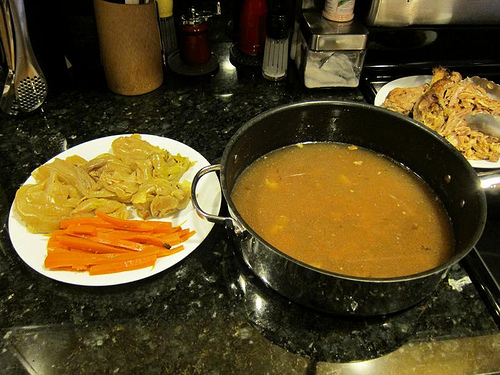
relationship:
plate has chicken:
[375, 73, 499, 171] [398, 74, 469, 119]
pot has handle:
[224, 103, 484, 316] [193, 164, 229, 229]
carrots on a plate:
[45, 214, 196, 277] [10, 133, 222, 289]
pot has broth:
[224, 103, 484, 316] [249, 163, 455, 253]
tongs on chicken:
[470, 71, 499, 138] [398, 74, 469, 119]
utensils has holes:
[3, 18, 48, 118] [21, 74, 45, 102]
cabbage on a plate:
[27, 146, 178, 206] [10, 133, 222, 289]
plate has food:
[10, 133, 222, 289] [36, 150, 172, 262]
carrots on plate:
[45, 214, 196, 277] [10, 133, 222, 289]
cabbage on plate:
[27, 146, 178, 206] [10, 133, 222, 289]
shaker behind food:
[263, 15, 294, 83] [36, 150, 172, 262]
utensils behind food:
[3, 18, 48, 118] [36, 150, 172, 262]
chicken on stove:
[398, 74, 469, 119] [366, 29, 499, 82]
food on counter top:
[36, 150, 172, 262] [3, 73, 500, 374]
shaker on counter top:
[263, 15, 294, 83] [3, 73, 500, 374]